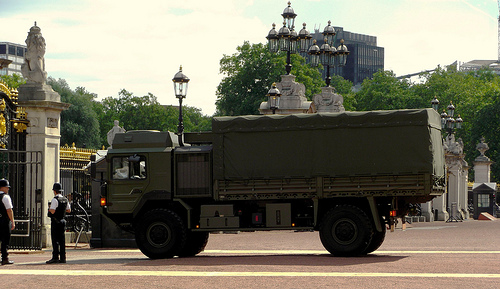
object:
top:
[331, 25, 388, 55]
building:
[308, 26, 383, 85]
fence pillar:
[17, 21, 69, 249]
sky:
[1, 0, 498, 117]